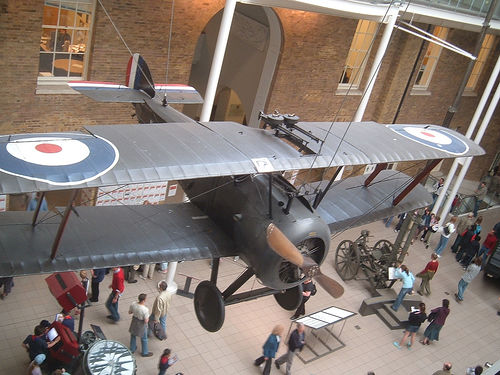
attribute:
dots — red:
[38, 141, 59, 156]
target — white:
[389, 110, 470, 161]